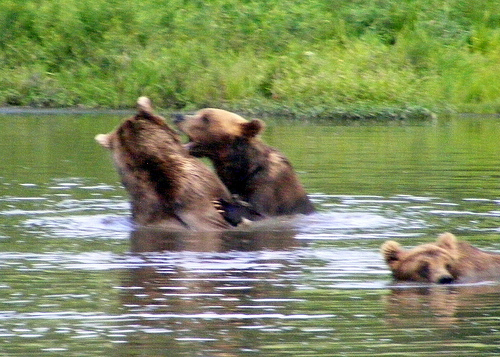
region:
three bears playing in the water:
[91, 92, 498, 290]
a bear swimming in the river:
[377, 226, 495, 289]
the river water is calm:
[2, 105, 492, 348]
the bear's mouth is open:
[168, 105, 260, 158]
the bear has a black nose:
[168, 106, 185, 123]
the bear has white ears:
[87, 90, 155, 152]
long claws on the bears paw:
[202, 190, 263, 230]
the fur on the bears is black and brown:
[88, 90, 316, 246]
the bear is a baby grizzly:
[171, 102, 316, 218]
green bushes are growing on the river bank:
[6, 3, 499, 127]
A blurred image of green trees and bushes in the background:
[0, 0, 499, 117]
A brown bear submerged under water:
[371, 226, 498, 306]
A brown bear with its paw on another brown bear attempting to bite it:
[171, 106, 326, 223]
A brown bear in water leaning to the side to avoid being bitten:
[67, 89, 204, 261]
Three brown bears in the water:
[43, 83, 499, 292]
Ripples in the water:
[46, 242, 232, 355]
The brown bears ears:
[86, 93, 160, 146]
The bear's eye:
[415, 258, 432, 277]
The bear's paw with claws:
[211, 195, 251, 227]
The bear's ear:
[236, 111, 271, 139]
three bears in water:
[100, 102, 496, 292]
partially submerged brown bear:
[384, 227, 496, 299]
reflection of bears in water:
[120, 229, 306, 326]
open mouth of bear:
[171, 109, 207, 156]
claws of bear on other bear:
[206, 191, 229, 221]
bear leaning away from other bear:
[111, 87, 218, 184]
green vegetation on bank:
[309, 48, 402, 110]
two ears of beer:
[379, 226, 462, 261]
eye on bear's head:
[195, 110, 222, 132]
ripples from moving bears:
[50, 194, 122, 234]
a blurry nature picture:
[38, 22, 485, 332]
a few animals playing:
[43, 61, 490, 331]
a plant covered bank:
[181, 73, 468, 133]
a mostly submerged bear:
[366, 207, 498, 304]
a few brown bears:
[67, 82, 344, 257]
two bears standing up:
[76, 83, 335, 286]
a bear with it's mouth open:
[166, 95, 281, 170]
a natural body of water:
[18, 86, 447, 354]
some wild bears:
[83, 85, 485, 315]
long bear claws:
[203, 194, 235, 224]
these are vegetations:
[51, 13, 411, 68]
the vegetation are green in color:
[13, 7, 426, 74]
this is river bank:
[244, 93, 496, 129]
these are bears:
[103, 82, 303, 226]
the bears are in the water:
[92, 95, 458, 312]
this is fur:
[121, 125, 188, 222]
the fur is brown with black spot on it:
[123, 117, 192, 212]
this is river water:
[31, 244, 261, 331]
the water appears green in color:
[307, 119, 469, 178]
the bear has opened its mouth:
[170, 107, 247, 149]